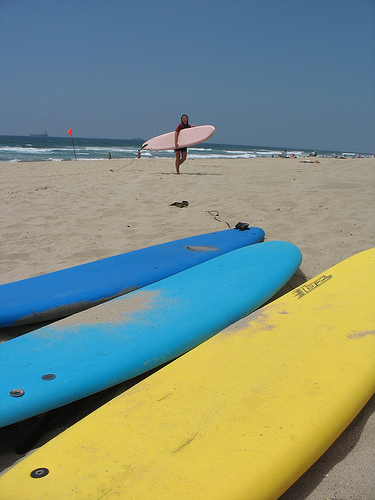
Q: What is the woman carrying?
A: A surfboard.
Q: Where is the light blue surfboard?
A: Laying in the sand.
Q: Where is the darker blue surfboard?
A: Laying in the sand.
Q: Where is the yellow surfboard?
A: Laying in the sand.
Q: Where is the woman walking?
A: On the beach.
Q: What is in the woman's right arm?
A: A pink surfboard.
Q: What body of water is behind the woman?
A: Ocean.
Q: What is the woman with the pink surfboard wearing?
A: A wet suit.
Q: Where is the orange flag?
A: On a pole in the sand.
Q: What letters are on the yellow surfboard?
A: Bz.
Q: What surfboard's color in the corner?
A: Yellow.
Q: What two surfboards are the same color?
A: Blue.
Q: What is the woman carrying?
A: Pink.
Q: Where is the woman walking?
A: Away from water.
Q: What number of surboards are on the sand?
A: 3.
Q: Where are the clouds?
A: No clouds.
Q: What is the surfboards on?
A: Beach.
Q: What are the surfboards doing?
A: In a row.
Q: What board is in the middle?
A: Light blue.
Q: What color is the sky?
A: Blue.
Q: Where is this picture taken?
A: A beach.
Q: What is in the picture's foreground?
A: Three surf boards.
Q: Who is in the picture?
A: A woman.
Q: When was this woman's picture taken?
A: The daytime.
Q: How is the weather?
A: Sunny.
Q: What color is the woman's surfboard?
A: Pink.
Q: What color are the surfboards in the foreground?
A: Yellow and blue.